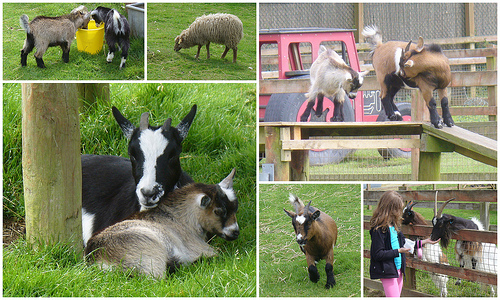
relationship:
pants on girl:
[379, 270, 403, 299] [369, 188, 443, 298]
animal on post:
[82, 104, 197, 247] [22, 85, 86, 262]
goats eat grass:
[173, 13, 243, 63] [149, 2, 256, 80]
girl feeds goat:
[354, 186, 415, 298] [416, 201, 498, 293]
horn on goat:
[134, 108, 156, 132] [80, 102, 202, 247]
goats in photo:
[173, 13, 243, 63] [14, 10, 465, 297]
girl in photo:
[370, 190, 443, 297] [14, 10, 465, 297]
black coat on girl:
[367, 219, 411, 280] [362, 189, 420, 297]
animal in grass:
[82, 104, 197, 247] [30, 245, 142, 297]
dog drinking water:
[20, 5, 91, 68] [72, 7, 110, 57]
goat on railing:
[298, 42, 371, 122] [260, 118, 497, 167]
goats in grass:
[65, 96, 243, 273] [33, 237, 161, 297]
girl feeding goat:
[370, 190, 443, 297] [423, 202, 494, 298]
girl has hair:
[370, 190, 443, 297] [371, 188, 392, 234]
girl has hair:
[370, 190, 443, 297] [358, 188, 385, 216]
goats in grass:
[173, 13, 243, 63] [149, 2, 256, 80]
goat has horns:
[63, 101, 208, 255] [102, 97, 209, 137]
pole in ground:
[8, 99, 103, 226] [17, 218, 126, 296]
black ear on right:
[107, 107, 135, 137] [162, 95, 232, 175]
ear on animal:
[176, 105, 196, 137] [82, 102, 197, 249]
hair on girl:
[368, 192, 403, 229] [370, 190, 443, 297]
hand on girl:
[401, 246, 412, 261] [370, 190, 443, 297]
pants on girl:
[380, 269, 404, 298] [367, 187, 435, 297]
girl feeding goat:
[370, 190, 443, 297] [421, 189, 498, 291]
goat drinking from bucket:
[296, 39, 351, 131] [67, 12, 106, 57]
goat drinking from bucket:
[361, 25, 462, 132] [67, 12, 106, 57]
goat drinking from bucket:
[279, 189, 354, 293] [67, 12, 106, 57]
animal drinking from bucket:
[82, 104, 197, 247] [67, 12, 106, 57]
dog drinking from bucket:
[20, 5, 91, 68] [67, 12, 106, 57]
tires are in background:
[271, 72, 434, 178] [268, 9, 404, 172]